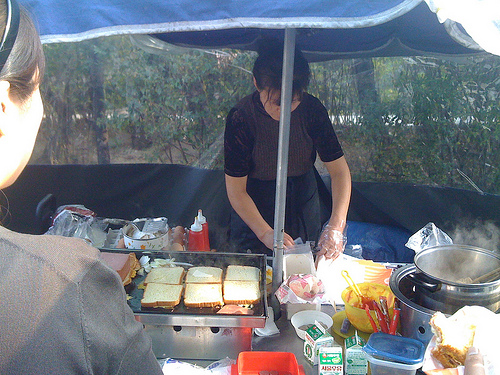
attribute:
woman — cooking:
[224, 37, 353, 260]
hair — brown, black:
[251, 42, 313, 107]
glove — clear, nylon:
[314, 214, 349, 262]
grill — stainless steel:
[98, 247, 268, 362]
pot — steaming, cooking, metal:
[388, 243, 498, 346]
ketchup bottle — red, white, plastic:
[187, 215, 205, 253]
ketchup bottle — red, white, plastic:
[194, 208, 211, 254]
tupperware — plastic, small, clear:
[362, 331, 425, 374]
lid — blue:
[363, 332, 426, 363]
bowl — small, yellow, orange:
[342, 283, 395, 333]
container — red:
[228, 351, 306, 374]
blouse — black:
[223, 92, 347, 182]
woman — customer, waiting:
[0, 0, 165, 374]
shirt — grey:
[0, 225, 165, 375]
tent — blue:
[16, 0, 500, 61]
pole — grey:
[269, 27, 298, 320]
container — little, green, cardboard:
[315, 345, 344, 375]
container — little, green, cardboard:
[344, 330, 368, 375]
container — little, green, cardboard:
[304, 321, 335, 366]